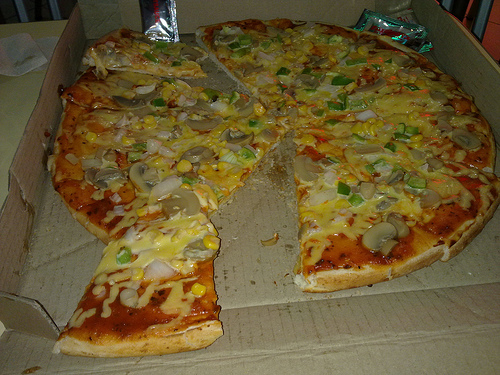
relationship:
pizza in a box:
[47, 17, 498, 354] [24, 4, 484, 352]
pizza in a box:
[47, 17, 498, 354] [20, 11, 340, 368]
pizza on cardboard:
[5, 28, 473, 364] [223, 192, 298, 300]